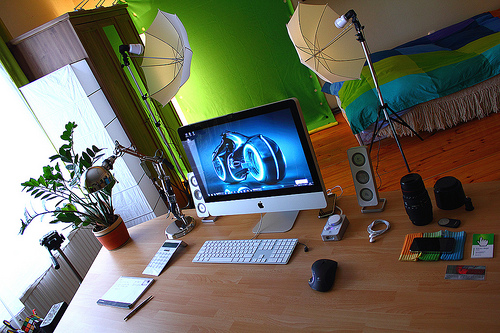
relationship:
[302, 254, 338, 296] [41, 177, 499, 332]
mouse on desk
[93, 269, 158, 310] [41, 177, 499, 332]
notepad on desk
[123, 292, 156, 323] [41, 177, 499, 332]
pen on desk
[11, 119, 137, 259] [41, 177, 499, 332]
houseplant on desk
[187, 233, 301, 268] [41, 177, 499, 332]
keyboard on desk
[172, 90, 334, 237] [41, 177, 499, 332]
monitor on desk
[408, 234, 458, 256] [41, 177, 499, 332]
iphone on desk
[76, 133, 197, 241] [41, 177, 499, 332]
lamp on desk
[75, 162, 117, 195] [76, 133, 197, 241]
head of lamp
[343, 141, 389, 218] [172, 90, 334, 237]
speakers by monitor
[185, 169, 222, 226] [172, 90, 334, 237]
speakers by monitor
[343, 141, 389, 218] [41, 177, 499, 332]
speakers on desk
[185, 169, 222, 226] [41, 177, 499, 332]
speakers on desk